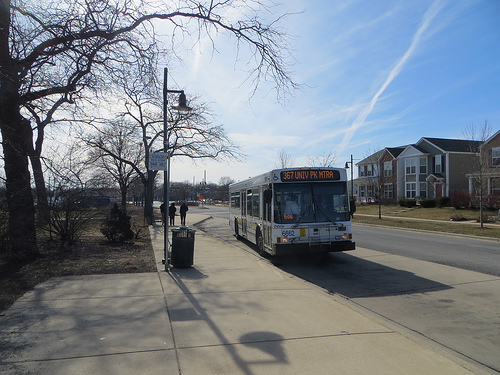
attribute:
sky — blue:
[0, 0, 499, 190]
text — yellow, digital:
[281, 169, 334, 180]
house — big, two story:
[397, 137, 486, 208]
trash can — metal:
[171, 224, 196, 269]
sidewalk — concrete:
[1, 212, 494, 374]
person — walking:
[180, 201, 190, 226]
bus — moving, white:
[228, 166, 357, 264]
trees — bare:
[1, 0, 500, 272]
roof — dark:
[411, 138, 488, 155]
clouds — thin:
[0, 0, 499, 186]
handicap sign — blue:
[272, 171, 281, 183]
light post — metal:
[162, 66, 193, 263]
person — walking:
[160, 201, 166, 227]